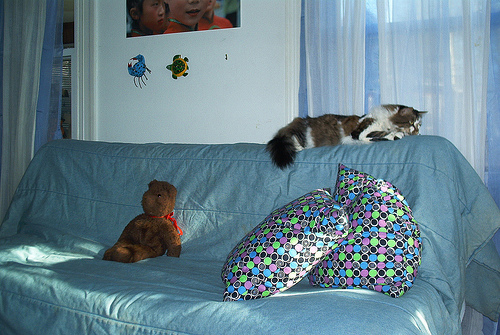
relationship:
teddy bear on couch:
[101, 178, 184, 265] [1, 135, 499, 334]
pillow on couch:
[220, 186, 350, 300] [1, 135, 499, 334]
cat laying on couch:
[266, 102, 428, 171] [1, 135, 499, 334]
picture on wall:
[124, 0, 243, 39] [99, 1, 289, 147]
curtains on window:
[305, 2, 485, 182] [287, 0, 500, 195]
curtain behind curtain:
[40, 0, 67, 154] [2, 0, 47, 216]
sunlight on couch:
[0, 243, 92, 267] [1, 135, 499, 334]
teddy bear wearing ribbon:
[101, 178, 184, 265] [153, 212, 183, 238]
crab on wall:
[125, 52, 152, 88] [99, 1, 289, 147]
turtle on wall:
[165, 53, 191, 80] [99, 1, 289, 147]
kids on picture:
[126, 0, 234, 38] [124, 0, 243, 39]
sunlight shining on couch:
[0, 243, 92, 267] [1, 135, 499, 334]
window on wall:
[44, 0, 102, 142] [99, 1, 289, 147]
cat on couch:
[266, 102, 428, 171] [1, 135, 499, 334]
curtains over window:
[305, 2, 485, 182] [287, 0, 500, 195]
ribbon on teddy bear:
[153, 212, 183, 238] [101, 178, 184, 265]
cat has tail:
[266, 102, 428, 171] [265, 121, 298, 169]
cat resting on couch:
[266, 102, 428, 171] [1, 135, 499, 334]